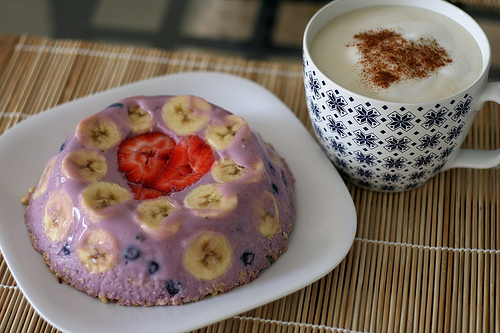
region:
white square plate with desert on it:
[0, 69, 357, 331]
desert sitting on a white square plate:
[26, 94, 297, 308]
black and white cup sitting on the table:
[301, 1, 498, 192]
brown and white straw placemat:
[2, 33, 497, 331]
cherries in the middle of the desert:
[122, 134, 213, 199]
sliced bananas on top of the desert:
[60, 99, 265, 228]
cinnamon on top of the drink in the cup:
[352, 27, 453, 88]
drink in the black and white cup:
[310, 0, 482, 98]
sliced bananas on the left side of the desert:
[30, 157, 117, 273]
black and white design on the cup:
[307, 90, 472, 183]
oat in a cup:
[303, 6, 499, 190]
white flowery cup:
[300, 7, 498, 193]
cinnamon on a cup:
[352, 29, 452, 94]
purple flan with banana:
[28, 89, 293, 314]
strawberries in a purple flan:
[121, 132, 208, 203]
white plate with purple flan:
[1, 72, 356, 332]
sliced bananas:
[34, 99, 279, 278]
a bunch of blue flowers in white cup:
[304, 76, 469, 187]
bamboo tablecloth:
[4, 33, 494, 332]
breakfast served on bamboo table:
[2, 5, 493, 329]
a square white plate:
[0, 68, 357, 331]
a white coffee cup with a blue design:
[300, 0, 498, 193]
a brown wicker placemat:
[0, 33, 497, 332]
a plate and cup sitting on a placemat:
[0, 0, 497, 330]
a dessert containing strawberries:
[25, 93, 294, 305]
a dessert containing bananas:
[20, 94, 295, 305]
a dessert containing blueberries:
[22, 94, 295, 306]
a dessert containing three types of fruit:
[25, 93, 297, 303]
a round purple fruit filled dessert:
[24, 92, 296, 306]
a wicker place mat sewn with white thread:
[1, 30, 498, 332]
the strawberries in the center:
[121, 130, 211, 201]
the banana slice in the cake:
[183, 225, 236, 277]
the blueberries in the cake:
[121, 238, 181, 300]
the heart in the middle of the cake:
[119, 130, 209, 197]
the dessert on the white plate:
[23, 86, 308, 314]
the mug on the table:
[300, 3, 497, 207]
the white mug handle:
[449, 87, 499, 179]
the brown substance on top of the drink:
[346, 25, 457, 94]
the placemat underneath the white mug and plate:
[358, 235, 499, 331]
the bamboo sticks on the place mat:
[379, 218, 497, 332]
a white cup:
[301, 0, 498, 197]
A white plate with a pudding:
[0, 69, 357, 330]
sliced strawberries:
[121, 133, 211, 195]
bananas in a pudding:
[123, 95, 247, 149]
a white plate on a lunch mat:
[0, 70, 360, 330]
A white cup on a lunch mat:
[301, 0, 497, 192]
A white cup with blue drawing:
[300, 1, 497, 190]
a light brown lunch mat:
[1, 32, 496, 332]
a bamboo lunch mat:
[1, 35, 495, 331]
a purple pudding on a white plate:
[22, 95, 297, 307]